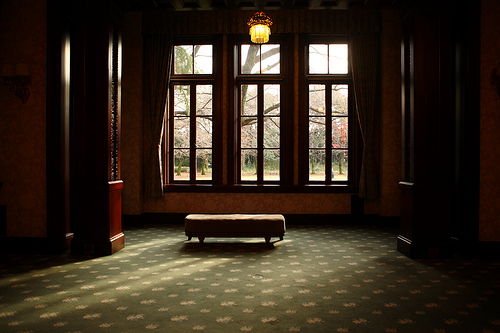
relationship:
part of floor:
[245, 271, 273, 289] [149, 251, 337, 332]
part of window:
[267, 85, 284, 98] [233, 84, 292, 154]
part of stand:
[262, 225, 281, 246] [235, 213, 285, 254]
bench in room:
[155, 178, 300, 266] [78, 54, 430, 332]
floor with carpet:
[149, 251, 337, 332] [41, 236, 447, 330]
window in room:
[233, 84, 292, 154] [78, 54, 430, 332]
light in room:
[246, 11, 273, 44] [78, 54, 430, 332]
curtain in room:
[127, 19, 198, 224] [78, 54, 430, 332]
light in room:
[227, 16, 280, 55] [78, 54, 430, 332]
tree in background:
[307, 114, 356, 177] [78, 54, 430, 332]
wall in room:
[366, 34, 416, 128] [78, 54, 430, 332]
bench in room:
[183, 213, 286, 247] [78, 54, 430, 332]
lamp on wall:
[0, 53, 49, 122] [366, 34, 416, 128]